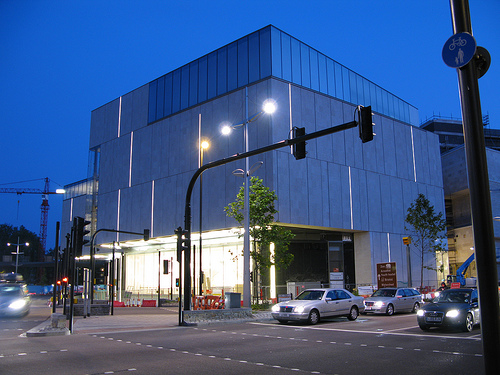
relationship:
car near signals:
[271, 287, 368, 324] [289, 127, 308, 161]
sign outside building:
[369, 262, 399, 287] [84, 25, 444, 309]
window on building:
[269, 24, 285, 79] [84, 25, 444, 309]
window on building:
[289, 33, 304, 85] [84, 25, 444, 309]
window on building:
[224, 42, 237, 92] [84, 25, 444, 309]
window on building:
[160, 73, 174, 120] [84, 25, 444, 309]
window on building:
[342, 63, 352, 104] [84, 25, 444, 309]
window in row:
[269, 24, 285, 79] [131, 22, 431, 132]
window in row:
[289, 33, 304, 85] [131, 22, 431, 132]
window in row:
[224, 42, 237, 92] [131, 22, 431, 132]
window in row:
[160, 73, 174, 120] [131, 22, 431, 132]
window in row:
[342, 63, 352, 104] [131, 22, 431, 132]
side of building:
[270, 24, 450, 314] [84, 25, 444, 309]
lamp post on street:
[214, 99, 281, 138] [3, 292, 484, 372]